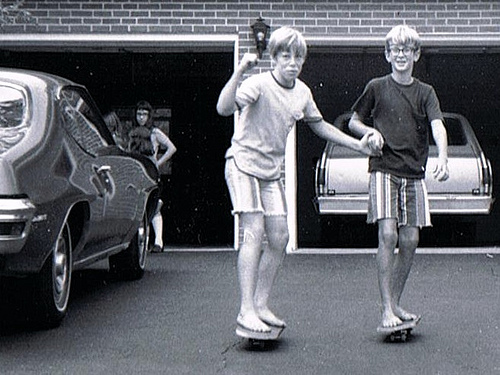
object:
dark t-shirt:
[351, 74, 447, 178]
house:
[0, 0, 500, 255]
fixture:
[249, 17, 270, 60]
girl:
[124, 100, 177, 253]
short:
[225, 157, 288, 217]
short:
[366, 171, 434, 229]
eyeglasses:
[385, 47, 416, 56]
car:
[312, 112, 494, 242]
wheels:
[386, 334, 407, 343]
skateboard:
[376, 313, 423, 342]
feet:
[382, 311, 403, 328]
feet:
[236, 312, 272, 332]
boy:
[216, 27, 383, 332]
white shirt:
[224, 70, 323, 182]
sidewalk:
[0, 247, 497, 375]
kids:
[215, 24, 449, 333]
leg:
[365, 186, 400, 311]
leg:
[225, 178, 265, 309]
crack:
[214, 337, 245, 375]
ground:
[0, 246, 500, 375]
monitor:
[249, 16, 270, 59]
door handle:
[97, 165, 111, 175]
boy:
[348, 25, 449, 327]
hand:
[432, 158, 450, 182]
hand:
[368, 131, 385, 151]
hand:
[359, 131, 383, 157]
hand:
[240, 53, 260, 71]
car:
[0, 67, 161, 328]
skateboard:
[235, 315, 285, 349]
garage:
[0, 41, 234, 247]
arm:
[156, 128, 177, 165]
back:
[311, 112, 493, 215]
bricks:
[0, 0, 500, 35]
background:
[0, 0, 500, 375]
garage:
[296, 45, 500, 248]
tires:
[18, 220, 73, 327]